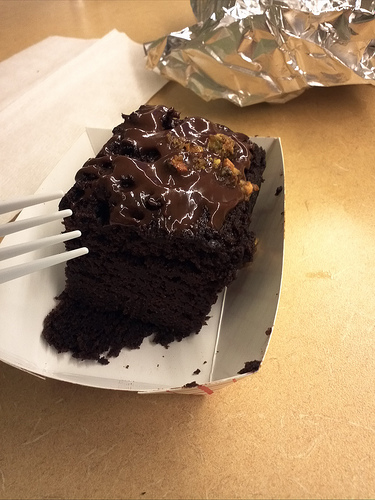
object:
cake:
[31, 99, 276, 367]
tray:
[0, 124, 288, 395]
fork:
[0, 197, 91, 290]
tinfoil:
[147, 0, 374, 110]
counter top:
[0, 1, 373, 498]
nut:
[222, 156, 243, 177]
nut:
[240, 181, 254, 198]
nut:
[166, 154, 189, 172]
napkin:
[0, 28, 168, 223]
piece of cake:
[238, 356, 262, 372]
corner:
[239, 357, 262, 374]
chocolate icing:
[79, 102, 253, 227]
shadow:
[0, 361, 209, 497]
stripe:
[195, 384, 216, 395]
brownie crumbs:
[182, 381, 198, 389]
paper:
[141, 2, 363, 111]